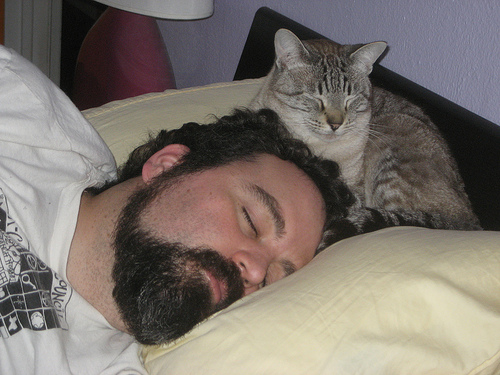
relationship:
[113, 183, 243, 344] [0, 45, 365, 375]
beard on man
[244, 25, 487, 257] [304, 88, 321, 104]
cat has eye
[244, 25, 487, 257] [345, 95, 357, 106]
cat has eye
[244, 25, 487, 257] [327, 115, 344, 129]
cat has nose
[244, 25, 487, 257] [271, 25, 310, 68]
cat has ear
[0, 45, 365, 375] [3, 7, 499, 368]
man in bed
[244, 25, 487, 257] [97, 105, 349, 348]
cat next to head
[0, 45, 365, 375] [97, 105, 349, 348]
man has head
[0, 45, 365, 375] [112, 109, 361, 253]
man has hair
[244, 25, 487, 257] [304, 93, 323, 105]
cat has eye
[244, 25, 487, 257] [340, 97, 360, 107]
cat has eye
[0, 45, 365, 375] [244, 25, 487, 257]
man next to cat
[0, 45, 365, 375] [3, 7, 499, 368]
man on bed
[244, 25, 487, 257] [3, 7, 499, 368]
cat on bed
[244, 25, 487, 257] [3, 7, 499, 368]
cat in bed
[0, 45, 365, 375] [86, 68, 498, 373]
man on pillow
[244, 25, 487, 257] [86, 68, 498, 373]
cat sleeping on pillow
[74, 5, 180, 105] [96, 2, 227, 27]
lamp with shade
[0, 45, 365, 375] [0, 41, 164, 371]
man wearing shirt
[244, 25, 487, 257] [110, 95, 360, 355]
cat sleeping next to head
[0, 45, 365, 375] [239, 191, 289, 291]
man with eyes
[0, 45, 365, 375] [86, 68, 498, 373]
man sleeping on pillow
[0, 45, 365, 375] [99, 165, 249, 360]
man has beard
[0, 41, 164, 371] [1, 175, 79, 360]
shirt has writing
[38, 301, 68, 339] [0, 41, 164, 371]
square on shirt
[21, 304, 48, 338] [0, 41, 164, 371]
square on shirt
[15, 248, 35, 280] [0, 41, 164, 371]
square on shirt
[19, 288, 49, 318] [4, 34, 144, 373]
square on shirt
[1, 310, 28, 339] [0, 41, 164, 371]
square on shirt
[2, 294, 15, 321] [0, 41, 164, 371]
square on shirt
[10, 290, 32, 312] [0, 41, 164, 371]
square on shirt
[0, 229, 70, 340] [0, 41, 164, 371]
square on shirt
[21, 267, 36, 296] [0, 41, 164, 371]
square on shirt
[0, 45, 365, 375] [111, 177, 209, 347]
man has beard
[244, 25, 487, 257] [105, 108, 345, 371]
cat above man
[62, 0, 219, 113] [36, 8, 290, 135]
lamp behind bed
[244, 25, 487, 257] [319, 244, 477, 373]
cat sleeping on bed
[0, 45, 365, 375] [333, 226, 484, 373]
man sleeping on bed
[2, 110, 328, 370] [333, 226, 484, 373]
man sleeping on bed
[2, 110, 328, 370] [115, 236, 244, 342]
man grew a beard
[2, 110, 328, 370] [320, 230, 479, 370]
man sleeping on a bed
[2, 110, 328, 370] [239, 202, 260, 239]
man closed h eyes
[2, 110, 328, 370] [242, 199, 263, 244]
man closed h eyes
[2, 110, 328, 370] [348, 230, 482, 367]
man resting on a pillow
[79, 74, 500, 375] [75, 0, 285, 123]
pillow on top of a bed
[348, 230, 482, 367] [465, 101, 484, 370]
pillow on top of a bed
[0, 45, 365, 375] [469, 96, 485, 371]
man sleeping on a bed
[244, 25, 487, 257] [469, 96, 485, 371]
cat sleeping on a bed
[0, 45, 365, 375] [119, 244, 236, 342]
man grew a beard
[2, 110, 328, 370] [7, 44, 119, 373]
man wearing a shirt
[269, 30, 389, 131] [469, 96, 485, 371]
cat sleeping on a bed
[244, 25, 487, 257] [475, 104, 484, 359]
cat sleeping on a bed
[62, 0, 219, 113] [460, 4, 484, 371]
lamp next to bed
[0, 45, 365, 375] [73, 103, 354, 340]
man resting head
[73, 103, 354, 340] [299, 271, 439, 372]
head on pillow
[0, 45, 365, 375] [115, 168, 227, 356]
man has beard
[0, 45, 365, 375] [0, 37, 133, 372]
man wearing shirt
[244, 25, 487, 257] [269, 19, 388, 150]
cat  head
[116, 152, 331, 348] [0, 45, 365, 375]
face on man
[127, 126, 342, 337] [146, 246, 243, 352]
face has beard